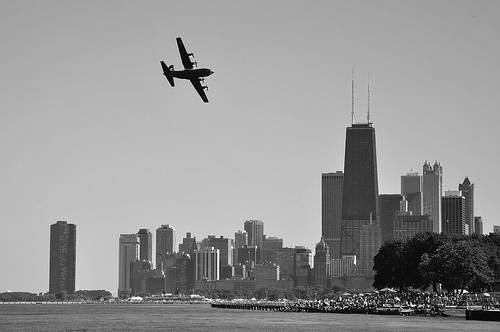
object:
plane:
[159, 37, 214, 103]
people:
[290, 284, 499, 317]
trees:
[372, 229, 499, 308]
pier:
[205, 301, 286, 311]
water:
[0, 304, 499, 331]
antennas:
[350, 67, 355, 126]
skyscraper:
[339, 64, 381, 291]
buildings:
[48, 66, 500, 291]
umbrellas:
[342, 286, 407, 299]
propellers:
[187, 51, 198, 69]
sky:
[1, 0, 499, 290]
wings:
[176, 37, 199, 71]